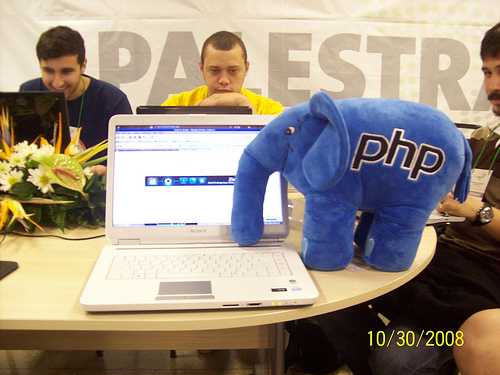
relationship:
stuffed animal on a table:
[226, 89, 475, 275] [1, 192, 442, 374]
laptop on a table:
[81, 111, 321, 313] [1, 192, 442, 374]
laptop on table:
[81, 111, 321, 313] [1, 192, 442, 374]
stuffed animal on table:
[226, 89, 475, 275] [1, 192, 442, 374]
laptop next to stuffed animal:
[81, 111, 321, 313] [226, 89, 475, 275]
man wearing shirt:
[147, 29, 292, 122] [152, 83, 293, 119]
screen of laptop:
[111, 123, 285, 231] [81, 111, 321, 313]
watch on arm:
[470, 200, 494, 229] [439, 182, 500, 238]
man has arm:
[414, 19, 500, 319] [439, 182, 500, 238]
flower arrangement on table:
[1, 104, 113, 241] [1, 192, 442, 374]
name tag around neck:
[462, 165, 493, 210] [489, 116, 500, 122]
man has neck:
[414, 19, 500, 319] [489, 116, 500, 122]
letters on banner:
[93, 26, 498, 125] [28, 12, 497, 133]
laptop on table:
[1, 84, 77, 155] [1, 192, 442, 374]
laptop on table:
[134, 100, 255, 116] [1, 192, 442, 374]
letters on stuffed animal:
[346, 126, 446, 185] [226, 89, 475, 275]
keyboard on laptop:
[103, 249, 294, 281] [81, 111, 321, 313]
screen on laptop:
[111, 123, 285, 231] [81, 111, 321, 313]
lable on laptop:
[269, 285, 290, 296] [81, 111, 321, 313]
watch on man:
[470, 200, 494, 229] [414, 19, 500, 319]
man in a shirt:
[147, 29, 292, 122] [152, 83, 293, 119]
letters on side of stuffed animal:
[346, 126, 446, 185] [226, 89, 475, 275]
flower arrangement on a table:
[1, 104, 113, 241] [1, 192, 442, 374]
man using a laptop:
[147, 29, 292, 122] [134, 100, 255, 116]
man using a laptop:
[10, 22, 139, 183] [1, 84, 77, 155]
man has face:
[10, 22, 139, 183] [38, 53, 82, 98]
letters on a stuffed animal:
[346, 126, 446, 185] [226, 89, 475, 275]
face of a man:
[38, 53, 82, 98] [10, 22, 139, 183]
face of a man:
[203, 49, 242, 97] [147, 29, 292, 122]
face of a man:
[481, 60, 500, 119] [414, 19, 500, 319]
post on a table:
[273, 319, 290, 375] [1, 192, 442, 374]